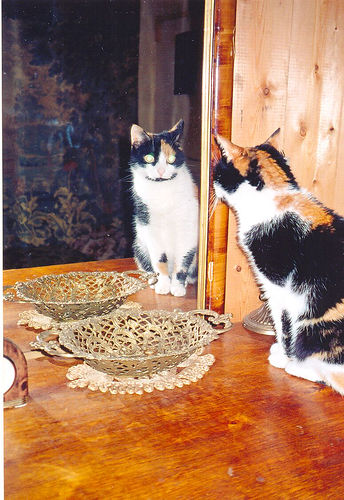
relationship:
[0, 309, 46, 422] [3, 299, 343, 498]
clock on dresser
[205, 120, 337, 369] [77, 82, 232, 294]
cat has reflection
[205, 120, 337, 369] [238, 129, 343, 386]
cat has fur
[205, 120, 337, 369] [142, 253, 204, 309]
cat has front paws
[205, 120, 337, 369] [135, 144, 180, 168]
cat has colorful eyes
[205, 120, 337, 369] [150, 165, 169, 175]
cat has nose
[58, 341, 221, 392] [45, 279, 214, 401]
doily under basket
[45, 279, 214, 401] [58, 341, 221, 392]
basket on doily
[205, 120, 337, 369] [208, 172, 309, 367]
cat has white fur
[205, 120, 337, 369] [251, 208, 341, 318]
cat has black fur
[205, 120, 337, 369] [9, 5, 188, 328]
cat sees mirror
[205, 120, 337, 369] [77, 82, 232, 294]
cat sees reflection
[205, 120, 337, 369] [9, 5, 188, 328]
cat looks in mirror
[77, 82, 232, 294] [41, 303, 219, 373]
reflection of bowl